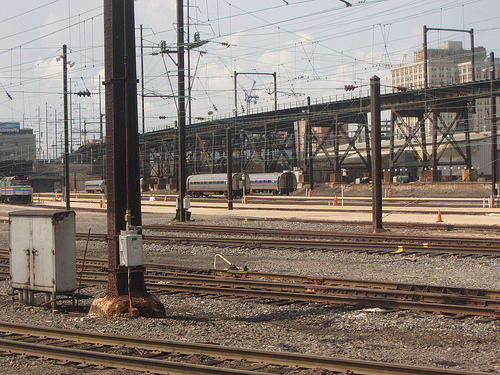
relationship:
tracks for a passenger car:
[2, 206, 498, 372] [186, 173, 250, 197]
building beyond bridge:
[391, 41, 500, 170] [139, 71, 499, 172]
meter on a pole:
[120, 215, 145, 270] [120, 2, 132, 215]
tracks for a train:
[2, 206, 498, 372] [86, 177, 110, 197]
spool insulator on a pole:
[52, 53, 66, 65] [63, 45, 72, 207]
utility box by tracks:
[7, 204, 78, 304] [2, 206, 498, 372]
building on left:
[1, 120, 40, 168] [3, 3, 110, 374]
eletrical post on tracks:
[173, 5, 193, 226] [2, 206, 498, 372]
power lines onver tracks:
[2, 5, 498, 119] [2, 206, 498, 372]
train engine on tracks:
[3, 170, 35, 208] [2, 206, 498, 372]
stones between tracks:
[181, 291, 457, 368] [2, 206, 498, 372]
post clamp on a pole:
[118, 209, 139, 223] [95, 8, 166, 318]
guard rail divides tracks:
[213, 195, 500, 209] [2, 206, 498, 372]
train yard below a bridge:
[2, 153, 497, 372] [139, 71, 499, 172]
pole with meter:
[90, 0, 164, 318] [120, 215, 145, 270]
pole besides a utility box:
[90, 0, 164, 318] [7, 204, 78, 304]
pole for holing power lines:
[90, 0, 164, 318] [2, 5, 498, 119]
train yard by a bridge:
[2, 153, 497, 372] [139, 71, 499, 172]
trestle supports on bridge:
[304, 111, 473, 188] [139, 71, 499, 172]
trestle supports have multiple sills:
[304, 111, 473, 188] [393, 160, 471, 169]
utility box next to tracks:
[7, 204, 78, 304] [2, 206, 498, 372]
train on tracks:
[86, 177, 110, 197] [2, 206, 498, 372]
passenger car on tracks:
[187, 170, 289, 197] [2, 206, 498, 372]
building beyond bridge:
[391, 41, 500, 170] [264, 134, 500, 176]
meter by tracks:
[120, 215, 145, 270] [2, 206, 498, 372]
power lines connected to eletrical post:
[2, 5, 498, 119] [173, 5, 193, 226]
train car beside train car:
[243, 170, 297, 195] [183, 170, 251, 198]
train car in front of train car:
[243, 172, 297, 195] [183, 168, 250, 199]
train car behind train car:
[243, 172, 297, 195] [179, 170, 253, 200]